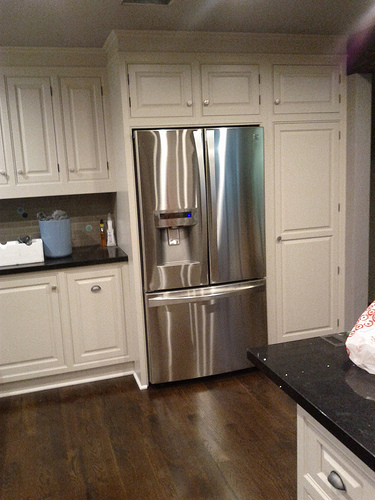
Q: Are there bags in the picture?
A: Yes, there is a bag.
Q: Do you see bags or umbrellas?
A: Yes, there is a bag.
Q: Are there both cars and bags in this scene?
A: No, there is a bag but no cars.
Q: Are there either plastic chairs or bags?
A: Yes, there is a plastic bag.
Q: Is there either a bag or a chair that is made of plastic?
A: Yes, the bag is made of plastic.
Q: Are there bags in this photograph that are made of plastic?
A: Yes, there is a bag that is made of plastic.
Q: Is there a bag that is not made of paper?
A: Yes, there is a bag that is made of plastic.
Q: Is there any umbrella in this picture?
A: No, there are no umbrellas.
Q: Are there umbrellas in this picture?
A: No, there are no umbrellas.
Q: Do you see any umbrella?
A: No, there are no umbrellas.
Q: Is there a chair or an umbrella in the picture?
A: No, there are no umbrellas or chairs.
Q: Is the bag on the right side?
A: Yes, the bag is on the right of the image.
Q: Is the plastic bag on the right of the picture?
A: Yes, the bag is on the right of the image.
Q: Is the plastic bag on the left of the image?
A: No, the bag is on the right of the image.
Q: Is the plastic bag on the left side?
A: No, the bag is on the right of the image.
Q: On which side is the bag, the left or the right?
A: The bag is on the right of the image.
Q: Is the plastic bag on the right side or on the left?
A: The bag is on the right of the image.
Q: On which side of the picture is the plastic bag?
A: The bag is on the right of the image.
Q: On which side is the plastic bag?
A: The bag is on the right of the image.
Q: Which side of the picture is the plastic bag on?
A: The bag is on the right of the image.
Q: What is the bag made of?
A: The bag is made of plastic.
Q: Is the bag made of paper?
A: No, the bag is made of plastic.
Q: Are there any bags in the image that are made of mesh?
A: No, there is a bag but it is made of plastic.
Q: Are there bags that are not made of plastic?
A: No, there is a bag but it is made of plastic.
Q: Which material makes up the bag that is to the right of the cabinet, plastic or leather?
A: The bag is made of plastic.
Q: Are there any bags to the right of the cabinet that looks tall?
A: Yes, there is a bag to the right of the cabinet.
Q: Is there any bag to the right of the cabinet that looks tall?
A: Yes, there is a bag to the right of the cabinet.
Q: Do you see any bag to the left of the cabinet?
A: No, the bag is to the right of the cabinet.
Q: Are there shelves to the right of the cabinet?
A: No, there is a bag to the right of the cabinet.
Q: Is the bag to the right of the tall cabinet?
A: Yes, the bag is to the right of the cabinet.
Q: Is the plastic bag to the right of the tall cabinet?
A: Yes, the bag is to the right of the cabinet.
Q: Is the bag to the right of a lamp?
A: No, the bag is to the right of the cabinet.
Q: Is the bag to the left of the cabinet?
A: No, the bag is to the right of the cabinet.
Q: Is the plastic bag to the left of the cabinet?
A: No, the bag is to the right of the cabinet.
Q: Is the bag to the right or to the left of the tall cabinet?
A: The bag is to the right of the cabinet.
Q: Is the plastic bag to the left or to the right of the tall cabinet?
A: The bag is to the right of the cabinet.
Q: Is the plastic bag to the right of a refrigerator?
A: Yes, the bag is to the right of a refrigerator.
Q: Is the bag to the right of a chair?
A: No, the bag is to the right of a refrigerator.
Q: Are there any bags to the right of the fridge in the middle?
A: Yes, there is a bag to the right of the refrigerator.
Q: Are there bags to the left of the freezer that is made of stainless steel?
A: No, the bag is to the right of the refrigerator.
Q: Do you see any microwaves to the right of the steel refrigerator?
A: No, there is a bag to the right of the freezer.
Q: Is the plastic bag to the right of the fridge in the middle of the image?
A: Yes, the bag is to the right of the freezer.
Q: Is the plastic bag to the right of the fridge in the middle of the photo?
A: Yes, the bag is to the right of the freezer.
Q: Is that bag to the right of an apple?
A: No, the bag is to the right of the freezer.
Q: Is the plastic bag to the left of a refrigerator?
A: No, the bag is to the right of a refrigerator.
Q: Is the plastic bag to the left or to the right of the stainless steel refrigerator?
A: The bag is to the right of the fridge.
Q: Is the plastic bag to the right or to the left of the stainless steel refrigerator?
A: The bag is to the right of the fridge.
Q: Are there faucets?
A: No, there are no faucets.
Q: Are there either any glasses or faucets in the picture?
A: No, there are no faucets or glasses.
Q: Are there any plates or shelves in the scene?
A: No, there are no shelves or plates.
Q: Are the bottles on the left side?
A: Yes, the bottles are on the left of the image.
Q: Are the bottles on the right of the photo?
A: No, the bottles are on the left of the image.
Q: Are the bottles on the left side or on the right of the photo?
A: The bottles are on the left of the image.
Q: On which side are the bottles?
A: The bottles are on the left of the image.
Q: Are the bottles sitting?
A: Yes, the bottles are sitting.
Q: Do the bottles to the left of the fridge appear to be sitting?
A: Yes, the bottles are sitting.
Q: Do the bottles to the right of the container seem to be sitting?
A: Yes, the bottles are sitting.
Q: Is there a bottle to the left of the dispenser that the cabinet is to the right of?
A: Yes, there are bottles to the left of the dispenser.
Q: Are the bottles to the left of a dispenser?
A: Yes, the bottles are to the left of a dispenser.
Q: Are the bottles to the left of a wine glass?
A: No, the bottles are to the left of a dispenser.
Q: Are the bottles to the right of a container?
A: Yes, the bottles are to the right of a container.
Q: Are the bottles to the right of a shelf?
A: No, the bottles are to the right of a container.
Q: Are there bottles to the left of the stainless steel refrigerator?
A: Yes, there are bottles to the left of the freezer.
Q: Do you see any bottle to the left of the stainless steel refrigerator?
A: Yes, there are bottles to the left of the freezer.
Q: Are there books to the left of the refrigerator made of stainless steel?
A: No, there are bottles to the left of the refrigerator.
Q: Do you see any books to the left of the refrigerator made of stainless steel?
A: No, there are bottles to the left of the refrigerator.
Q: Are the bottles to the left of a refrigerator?
A: Yes, the bottles are to the left of a refrigerator.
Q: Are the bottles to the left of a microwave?
A: No, the bottles are to the left of a refrigerator.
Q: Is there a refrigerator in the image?
A: Yes, there is a refrigerator.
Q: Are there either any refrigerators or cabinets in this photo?
A: Yes, there is a refrigerator.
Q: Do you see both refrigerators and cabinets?
A: Yes, there are both a refrigerator and cabinets.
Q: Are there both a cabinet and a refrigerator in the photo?
A: Yes, there are both a refrigerator and a cabinet.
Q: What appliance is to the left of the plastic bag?
A: The appliance is a refrigerator.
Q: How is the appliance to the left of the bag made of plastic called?
A: The appliance is a refrigerator.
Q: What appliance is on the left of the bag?
A: The appliance is a refrigerator.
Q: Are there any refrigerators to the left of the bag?
A: Yes, there is a refrigerator to the left of the bag.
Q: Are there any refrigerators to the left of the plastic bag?
A: Yes, there is a refrigerator to the left of the bag.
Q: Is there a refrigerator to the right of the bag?
A: No, the refrigerator is to the left of the bag.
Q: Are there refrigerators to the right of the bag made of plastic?
A: No, the refrigerator is to the left of the bag.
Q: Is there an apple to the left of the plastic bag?
A: No, there is a refrigerator to the left of the bag.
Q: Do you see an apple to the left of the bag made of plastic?
A: No, there is a refrigerator to the left of the bag.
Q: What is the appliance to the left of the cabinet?
A: The appliance is a refrigerator.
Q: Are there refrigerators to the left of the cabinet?
A: Yes, there is a refrigerator to the left of the cabinet.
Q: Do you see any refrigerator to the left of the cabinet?
A: Yes, there is a refrigerator to the left of the cabinet.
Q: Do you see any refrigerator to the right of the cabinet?
A: No, the refrigerator is to the left of the cabinet.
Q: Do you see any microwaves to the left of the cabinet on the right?
A: No, there is a refrigerator to the left of the cabinet.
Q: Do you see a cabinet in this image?
A: Yes, there is a cabinet.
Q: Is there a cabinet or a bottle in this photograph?
A: Yes, there is a cabinet.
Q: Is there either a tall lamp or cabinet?
A: Yes, there is a tall cabinet.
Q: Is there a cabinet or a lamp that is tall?
A: Yes, the cabinet is tall.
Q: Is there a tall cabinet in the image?
A: Yes, there is a tall cabinet.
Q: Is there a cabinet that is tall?
A: Yes, there is a cabinet that is tall.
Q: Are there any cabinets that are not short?
A: Yes, there is a tall cabinet.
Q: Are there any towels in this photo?
A: No, there are no towels.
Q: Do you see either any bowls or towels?
A: No, there are no towels or bowls.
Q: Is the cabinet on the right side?
A: Yes, the cabinet is on the right of the image.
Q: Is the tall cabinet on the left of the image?
A: No, the cabinet is on the right of the image.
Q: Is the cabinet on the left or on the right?
A: The cabinet is on the right of the image.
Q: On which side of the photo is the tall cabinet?
A: The cabinet is on the right of the image.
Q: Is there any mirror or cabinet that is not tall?
A: No, there is a cabinet but it is tall.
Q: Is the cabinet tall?
A: Yes, the cabinet is tall.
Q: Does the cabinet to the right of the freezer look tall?
A: Yes, the cabinet is tall.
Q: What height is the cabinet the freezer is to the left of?
A: The cabinet is tall.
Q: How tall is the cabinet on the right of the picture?
A: The cabinet is tall.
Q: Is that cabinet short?
A: No, the cabinet is tall.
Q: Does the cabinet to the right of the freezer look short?
A: No, the cabinet is tall.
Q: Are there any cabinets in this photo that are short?
A: No, there is a cabinet but it is tall.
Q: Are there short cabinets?
A: No, there is a cabinet but it is tall.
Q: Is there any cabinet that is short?
A: No, there is a cabinet but it is tall.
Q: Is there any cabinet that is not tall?
A: No, there is a cabinet but it is tall.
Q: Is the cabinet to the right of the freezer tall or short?
A: The cabinet is tall.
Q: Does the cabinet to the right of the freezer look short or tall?
A: The cabinet is tall.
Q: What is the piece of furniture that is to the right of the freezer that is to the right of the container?
A: The piece of furniture is a cabinet.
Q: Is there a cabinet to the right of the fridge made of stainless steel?
A: Yes, there is a cabinet to the right of the freezer.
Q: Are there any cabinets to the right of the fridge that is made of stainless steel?
A: Yes, there is a cabinet to the right of the freezer.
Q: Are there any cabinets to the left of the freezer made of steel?
A: No, the cabinet is to the right of the fridge.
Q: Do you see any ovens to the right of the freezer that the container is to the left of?
A: No, there is a cabinet to the right of the refrigerator.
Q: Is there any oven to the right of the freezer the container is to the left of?
A: No, there is a cabinet to the right of the refrigerator.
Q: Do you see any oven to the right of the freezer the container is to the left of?
A: No, there is a cabinet to the right of the refrigerator.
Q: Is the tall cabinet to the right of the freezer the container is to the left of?
A: Yes, the cabinet is to the right of the fridge.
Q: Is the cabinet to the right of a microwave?
A: No, the cabinet is to the right of the fridge.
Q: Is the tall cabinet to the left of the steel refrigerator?
A: No, the cabinet is to the right of the refrigerator.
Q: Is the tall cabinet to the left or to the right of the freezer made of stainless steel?
A: The cabinet is to the right of the fridge.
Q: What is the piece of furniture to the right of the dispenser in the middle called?
A: The piece of furniture is a cabinet.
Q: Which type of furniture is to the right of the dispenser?
A: The piece of furniture is a cabinet.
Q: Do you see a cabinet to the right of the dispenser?
A: Yes, there is a cabinet to the right of the dispenser.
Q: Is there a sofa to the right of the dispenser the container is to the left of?
A: No, there is a cabinet to the right of the dispenser.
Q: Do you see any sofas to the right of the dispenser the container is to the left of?
A: No, there is a cabinet to the right of the dispenser.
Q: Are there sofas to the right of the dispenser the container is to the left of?
A: No, there is a cabinet to the right of the dispenser.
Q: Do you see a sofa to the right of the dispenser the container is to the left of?
A: No, there is a cabinet to the right of the dispenser.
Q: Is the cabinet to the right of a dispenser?
A: Yes, the cabinet is to the right of a dispenser.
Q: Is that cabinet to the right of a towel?
A: No, the cabinet is to the right of a dispenser.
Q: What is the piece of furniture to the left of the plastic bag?
A: The piece of furniture is a cabinet.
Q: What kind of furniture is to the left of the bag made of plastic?
A: The piece of furniture is a cabinet.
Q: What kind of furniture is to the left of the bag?
A: The piece of furniture is a cabinet.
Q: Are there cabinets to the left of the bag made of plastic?
A: Yes, there is a cabinet to the left of the bag.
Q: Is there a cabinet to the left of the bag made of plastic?
A: Yes, there is a cabinet to the left of the bag.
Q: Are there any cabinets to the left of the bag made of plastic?
A: Yes, there is a cabinet to the left of the bag.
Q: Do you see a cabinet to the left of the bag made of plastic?
A: Yes, there is a cabinet to the left of the bag.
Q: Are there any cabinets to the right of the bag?
A: No, the cabinet is to the left of the bag.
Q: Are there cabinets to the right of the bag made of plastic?
A: No, the cabinet is to the left of the bag.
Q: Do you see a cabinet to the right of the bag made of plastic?
A: No, the cabinet is to the left of the bag.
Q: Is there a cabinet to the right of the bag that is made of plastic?
A: No, the cabinet is to the left of the bag.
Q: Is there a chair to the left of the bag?
A: No, there is a cabinet to the left of the bag.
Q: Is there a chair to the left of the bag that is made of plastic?
A: No, there is a cabinet to the left of the bag.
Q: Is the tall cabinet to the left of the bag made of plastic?
A: Yes, the cabinet is to the left of the bag.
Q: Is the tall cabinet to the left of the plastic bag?
A: Yes, the cabinet is to the left of the bag.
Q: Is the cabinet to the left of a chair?
A: No, the cabinet is to the left of the bag.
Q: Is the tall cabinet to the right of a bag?
A: No, the cabinet is to the left of a bag.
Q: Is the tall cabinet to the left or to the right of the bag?
A: The cabinet is to the left of the bag.